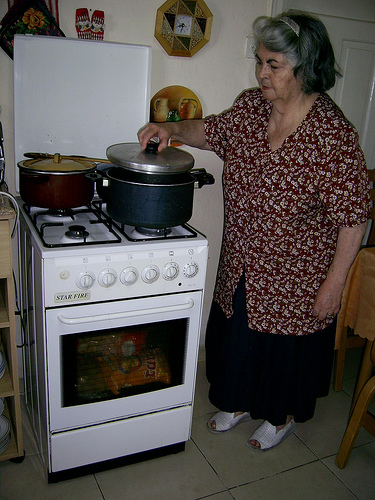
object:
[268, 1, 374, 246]
door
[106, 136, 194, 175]
lid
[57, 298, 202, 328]
handle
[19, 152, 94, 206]
pot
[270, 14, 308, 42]
headband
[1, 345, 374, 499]
floor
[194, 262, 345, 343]
skirt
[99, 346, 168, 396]
potato chips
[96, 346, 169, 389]
bag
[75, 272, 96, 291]
knob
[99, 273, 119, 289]
knob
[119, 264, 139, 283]
knob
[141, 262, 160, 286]
knob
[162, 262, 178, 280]
knob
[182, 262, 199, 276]
knob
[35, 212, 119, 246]
burner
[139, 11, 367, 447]
woman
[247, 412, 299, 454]
shoe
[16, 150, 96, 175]
lid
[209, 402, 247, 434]
right shoe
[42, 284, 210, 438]
door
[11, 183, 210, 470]
stove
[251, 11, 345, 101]
hair